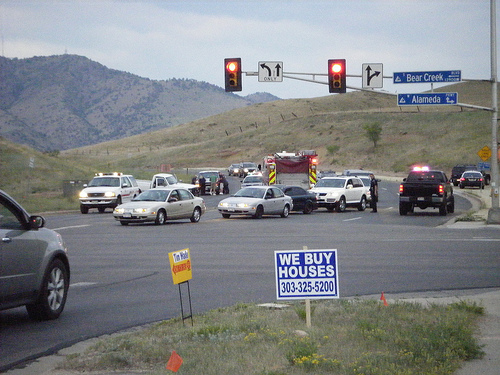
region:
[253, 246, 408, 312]
white and blue sign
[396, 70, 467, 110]
blue and white street signs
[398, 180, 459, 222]
brake lights of pick up truck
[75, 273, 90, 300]
white lines on street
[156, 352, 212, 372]
red utility company flag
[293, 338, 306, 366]
yellow flowers in dry grass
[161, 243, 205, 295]
sign is yellow and white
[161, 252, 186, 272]
sign is yellow and red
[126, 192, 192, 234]
small silver sedan on street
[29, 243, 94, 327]
front black tire on vehicle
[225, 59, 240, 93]
red traffic light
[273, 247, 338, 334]
ad for buying houses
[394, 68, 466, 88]
blue street sign for Bear Creek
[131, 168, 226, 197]
auto accident that just happened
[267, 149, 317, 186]
emergency vehicle responding to accident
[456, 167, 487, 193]
police car pulled to side of road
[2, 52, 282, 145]
high rocky hill in background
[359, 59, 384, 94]
sign saying straight or right only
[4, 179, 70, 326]
car waiting while accident is taken care of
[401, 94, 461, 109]
blue street sign reading Alemeda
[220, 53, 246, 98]
Red Traffic light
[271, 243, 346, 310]
We buy houses sign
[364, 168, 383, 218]
policeman looking at wreck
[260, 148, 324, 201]
fire truck working accident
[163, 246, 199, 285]
yellow sign with arrow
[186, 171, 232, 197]
emergency personel providing care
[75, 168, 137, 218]
police car with lights on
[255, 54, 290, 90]
lane direction sign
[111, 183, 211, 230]
silver car waiting at red light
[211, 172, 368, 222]
cars going around fire truck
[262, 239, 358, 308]
A blue and white sign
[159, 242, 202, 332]
A yellow sign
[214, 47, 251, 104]
A red traffic light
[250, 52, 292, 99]
Black and White traffic sign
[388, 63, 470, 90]
A street sign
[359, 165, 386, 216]
A police officer on the street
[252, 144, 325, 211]
A fire engine on the road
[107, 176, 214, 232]
A gold car on the road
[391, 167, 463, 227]
A stopped truck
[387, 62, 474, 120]
Two street signs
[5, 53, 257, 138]
the mountain in the distance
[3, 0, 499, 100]
the sky above the mountains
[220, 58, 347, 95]
the traffic lights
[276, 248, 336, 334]
the sign in the grass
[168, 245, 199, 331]
the yellow sign in the grass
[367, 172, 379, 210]
the man standing on the road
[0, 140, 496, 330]
the vehicles on the road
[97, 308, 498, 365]
the small patch of grass near the road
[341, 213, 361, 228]
the white line on the road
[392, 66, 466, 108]
the blue street signs